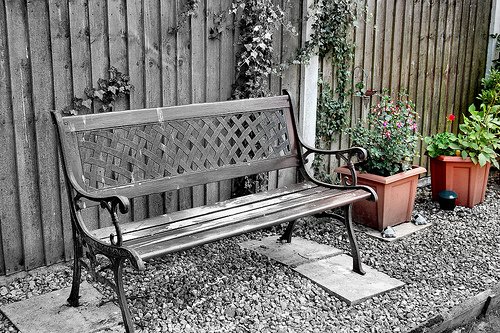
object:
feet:
[346, 264, 370, 275]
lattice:
[76, 106, 293, 193]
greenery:
[292, 0, 375, 219]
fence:
[0, 1, 494, 277]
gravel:
[221, 308, 237, 319]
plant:
[59, 65, 139, 116]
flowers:
[442, 114, 457, 122]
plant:
[337, 101, 427, 178]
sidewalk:
[0, 175, 498, 333]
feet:
[56, 293, 88, 309]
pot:
[427, 151, 491, 207]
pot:
[333, 160, 425, 231]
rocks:
[0, 283, 10, 296]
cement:
[292, 254, 400, 299]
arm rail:
[287, 97, 375, 190]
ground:
[2, 164, 499, 333]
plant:
[420, 94, 498, 174]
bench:
[47, 89, 376, 333]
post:
[297, 0, 317, 182]